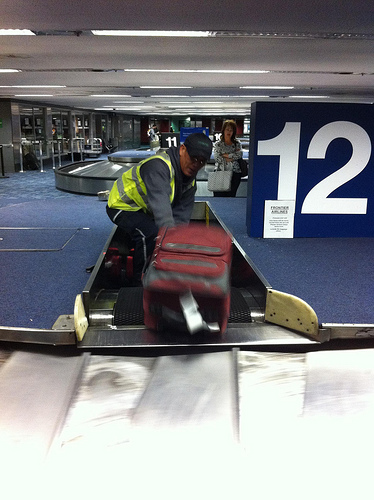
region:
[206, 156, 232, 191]
Woman's medium sized grey handbag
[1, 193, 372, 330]
Blue carpet on an airport luggage carousel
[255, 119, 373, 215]
Large number 12 in white writing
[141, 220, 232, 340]
Red suitcase exiting the conveyer belt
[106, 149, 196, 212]
Airport worker's bright yellow safety vest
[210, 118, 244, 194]
Woman standing with her arms crossed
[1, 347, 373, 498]
Silver circular belt of an airport luggage carousel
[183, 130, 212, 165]
Dark navy blue man's baseball cap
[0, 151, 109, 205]
Blue patterened carpeting of an airport floor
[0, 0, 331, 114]
Rows of illuminated ceiling lights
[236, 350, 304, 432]
silver colored belt peice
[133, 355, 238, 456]
silver colored belt peice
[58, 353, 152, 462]
silver colored belt peice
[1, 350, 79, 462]
silver colored belt peice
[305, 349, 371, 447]
silver colored belt peice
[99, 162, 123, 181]
silver colored belt peice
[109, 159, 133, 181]
silver colored belt peice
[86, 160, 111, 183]
silver colored belt peice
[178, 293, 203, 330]
white tag on suitcase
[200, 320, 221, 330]
white tag on suitcase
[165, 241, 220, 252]
black stripe on suitcase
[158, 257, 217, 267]
black stripe on suitcase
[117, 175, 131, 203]
silver stripe on vest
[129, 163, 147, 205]
silver stripe on vest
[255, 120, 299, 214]
white number on sign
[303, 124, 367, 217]
white number on sign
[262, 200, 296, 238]
white paper on sign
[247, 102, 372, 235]
large blue 12 sign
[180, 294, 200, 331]
white tag on bag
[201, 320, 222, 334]
white tag on bag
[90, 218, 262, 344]
red suitcase on conveyer belt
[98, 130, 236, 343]
baggage handler and red suitcase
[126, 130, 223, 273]
Man wearing blue cap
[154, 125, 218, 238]
man in blue cap wearing glasses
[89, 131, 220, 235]
Man wearing gray and yellow striped vest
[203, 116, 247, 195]
woman holding white tote bag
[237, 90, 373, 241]
Airport baggage carousel number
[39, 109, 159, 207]
empty baggage carousel at airport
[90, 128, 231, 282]
Man wearing gray shirt and blue pants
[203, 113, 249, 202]
woman in floral top holding white purse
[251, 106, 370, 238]
Number 12 on white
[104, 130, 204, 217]
Man wearing a yellow safety vest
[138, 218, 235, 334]
The luggage is red and black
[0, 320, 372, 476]
The conveyor belt is silver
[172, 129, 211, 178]
The man is wearing a hat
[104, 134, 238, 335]
The man is dragging the luggage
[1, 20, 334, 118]
Long narrow lights on the ceiling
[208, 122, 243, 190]
Woman holding a white bag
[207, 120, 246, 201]
The woman is standing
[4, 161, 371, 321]
The carpet is blue